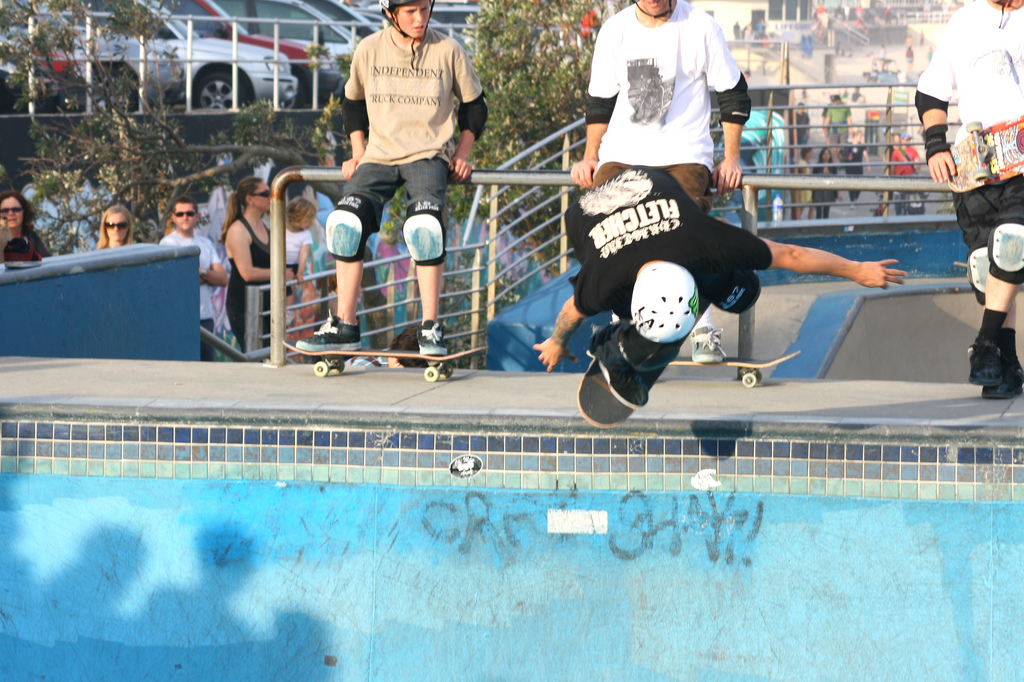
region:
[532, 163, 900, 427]
the skateboarder is facing down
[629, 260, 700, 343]
the helmet is mostly white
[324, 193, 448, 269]
the knee pads are black, white and blue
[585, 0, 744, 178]
the shirt is white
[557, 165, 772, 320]
the shirt is black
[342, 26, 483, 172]
the shirt is light brown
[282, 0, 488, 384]
the boy standing on the skateboard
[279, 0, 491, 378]
the boy is wearing knee pads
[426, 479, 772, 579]
Graffiti on the inside of an empty swimming pool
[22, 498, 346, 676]
A reflection of three people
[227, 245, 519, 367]
A gray metal gate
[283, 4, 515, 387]
A skateboarder in a brown shirt and blue knee pads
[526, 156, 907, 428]
A skater performing a trick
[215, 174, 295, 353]
A woman in a black tank top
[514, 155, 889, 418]
skateboarder wearing black and white shirt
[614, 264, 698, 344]
white helmet skateboarder is wearing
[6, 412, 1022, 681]
blue ramp skateboarder is on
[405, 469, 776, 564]
black lettering spray painted on the blue ramp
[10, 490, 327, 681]
shadows on the blue ramp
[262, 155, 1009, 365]
railing on the top of the ramp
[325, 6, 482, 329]
skateboarder wearing light brown shirt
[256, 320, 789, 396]
skateboards with white wheels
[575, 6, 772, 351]
skateboarder wearing brown shorts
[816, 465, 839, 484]
brick on the wall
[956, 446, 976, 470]
brick on the wall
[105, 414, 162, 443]
brick on the wall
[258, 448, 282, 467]
brick on the wall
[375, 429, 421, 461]
brick on the wall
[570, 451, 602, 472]
brick on the wall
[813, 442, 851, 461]
brick on the wall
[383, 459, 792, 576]
THE GRAFFITI IS ON THE POOL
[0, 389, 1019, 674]
THE POOL IS EMPTY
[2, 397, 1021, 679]
THE POOL IS BLUE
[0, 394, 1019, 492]
THE TILES ARE BLUE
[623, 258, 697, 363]
THE HELMET IS WHITE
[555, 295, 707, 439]
THIS IS A SKATEBOARD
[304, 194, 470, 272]
THE GUY IS WEARING KNEE PADS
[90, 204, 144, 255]
THE WOMAN IS WEARING SUNGLASSES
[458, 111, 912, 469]
man doing a trick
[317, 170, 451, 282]
a pair of knee pads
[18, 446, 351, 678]
shadows on the pike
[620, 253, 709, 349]
Helmet on a man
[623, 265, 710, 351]
White helmet on a man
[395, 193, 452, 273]
Knee pad on a man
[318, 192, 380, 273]
Knee pad on a man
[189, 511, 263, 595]
Head of a shadow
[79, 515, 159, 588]
Head of a shadow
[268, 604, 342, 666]
Head of a shadow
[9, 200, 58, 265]
A person is standing up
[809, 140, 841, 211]
A person is standing up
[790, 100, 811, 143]
A person is standing up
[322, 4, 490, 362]
A person is playing.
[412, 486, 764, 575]
graffiti written on wall of pool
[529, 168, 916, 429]
Skateboarder performing tricks in pool